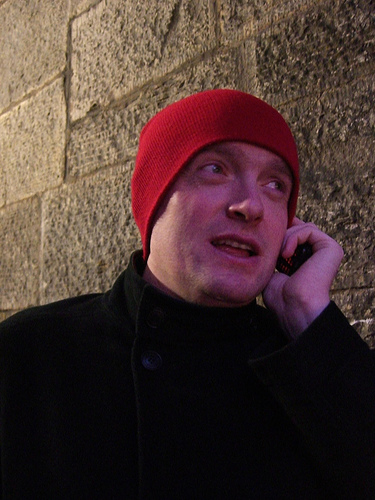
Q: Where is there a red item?
A: On head.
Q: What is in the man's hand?
A: A phone.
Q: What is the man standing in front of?
A: A stone wall.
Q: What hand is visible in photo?
A: Left.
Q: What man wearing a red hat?
A: Man with phone.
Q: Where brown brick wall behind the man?
A: On left side.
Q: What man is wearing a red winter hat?
A: Man with black jacket.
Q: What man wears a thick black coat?
A: Man with cell phone.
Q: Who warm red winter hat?
A: Man with phone.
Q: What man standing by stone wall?
A: Man with facial smile.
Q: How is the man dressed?
A: In a winter jacket.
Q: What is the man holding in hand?
A: Cell phone.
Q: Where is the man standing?
A: Next to a wall.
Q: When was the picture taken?
A: During the daytime.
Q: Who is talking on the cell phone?
A: A man.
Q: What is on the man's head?
A: Red hat.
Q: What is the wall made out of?
A: Stones.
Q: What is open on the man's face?
A: His mouth.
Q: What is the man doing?
A: Talking on his cell phone.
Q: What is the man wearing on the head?
A: Red hat.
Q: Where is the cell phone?
A: In the man's left hand.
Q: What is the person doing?
A: Talking on the phone.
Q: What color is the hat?
A: Red.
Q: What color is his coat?
A: Black.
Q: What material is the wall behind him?
A: Stone.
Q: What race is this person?
A: Caucasian.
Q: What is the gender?
A: Male.